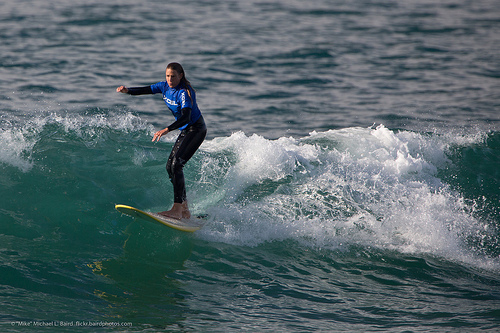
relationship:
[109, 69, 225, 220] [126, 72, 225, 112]
woman has hair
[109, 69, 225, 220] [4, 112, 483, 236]
woman on a wave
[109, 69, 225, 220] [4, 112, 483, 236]
woman riding a wave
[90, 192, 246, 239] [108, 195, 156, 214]
surfboard has a nose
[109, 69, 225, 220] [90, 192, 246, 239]
woman standing on surfboard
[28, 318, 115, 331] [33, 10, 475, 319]
michael bard on photo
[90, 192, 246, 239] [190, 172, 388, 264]
surfboard making a wake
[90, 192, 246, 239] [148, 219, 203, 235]
surfboard has an edge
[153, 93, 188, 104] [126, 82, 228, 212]
letters are on wetsuit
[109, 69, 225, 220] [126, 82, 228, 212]
woman wearing a wetsuit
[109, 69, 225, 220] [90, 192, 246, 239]
woman on surfboard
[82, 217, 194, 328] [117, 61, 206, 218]
reflection of surfer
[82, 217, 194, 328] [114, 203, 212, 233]
reflection of board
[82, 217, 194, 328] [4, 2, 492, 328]
reflection in water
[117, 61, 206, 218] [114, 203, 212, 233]
surfer on board